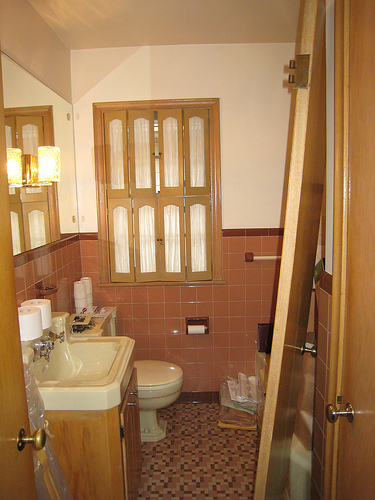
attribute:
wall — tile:
[156, 206, 324, 424]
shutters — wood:
[90, 98, 241, 289]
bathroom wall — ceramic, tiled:
[17, 234, 278, 391]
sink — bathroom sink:
[20, 310, 137, 409]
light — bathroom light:
[12, 142, 65, 204]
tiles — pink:
[178, 280, 291, 346]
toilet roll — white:
[183, 321, 206, 337]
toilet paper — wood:
[186, 317, 208, 335]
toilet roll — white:
[17, 304, 48, 340]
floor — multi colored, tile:
[134, 401, 290, 499]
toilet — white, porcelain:
[128, 358, 186, 441]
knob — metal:
[290, 340, 317, 363]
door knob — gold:
[13, 425, 47, 455]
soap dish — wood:
[35, 280, 62, 297]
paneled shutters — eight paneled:
[104, 106, 212, 274]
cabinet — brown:
[90, 95, 227, 291]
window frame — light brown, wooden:
[90, 97, 224, 283]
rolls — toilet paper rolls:
[18, 286, 55, 344]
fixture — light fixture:
[26, 145, 62, 186]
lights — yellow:
[4, 147, 58, 192]